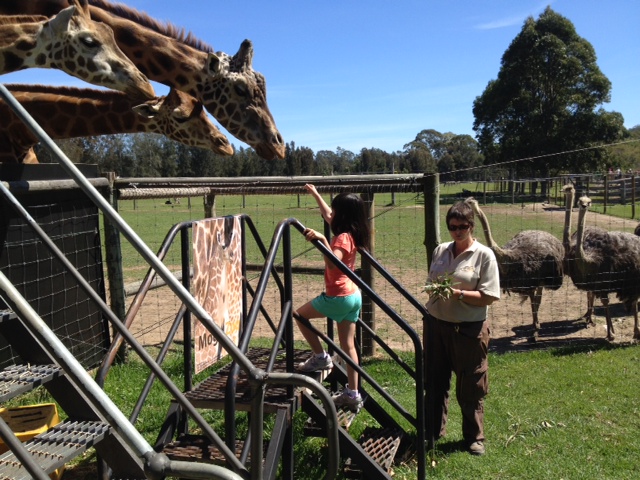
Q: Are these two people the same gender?
A: Yes, all the people are female.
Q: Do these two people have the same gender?
A: Yes, all the people are female.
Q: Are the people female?
A: Yes, all the people are female.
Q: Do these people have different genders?
A: No, all the people are female.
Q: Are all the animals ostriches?
A: No, there are both giraffes and ostriches.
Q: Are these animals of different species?
A: Yes, they are giraffes and ostriches.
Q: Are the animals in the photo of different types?
A: Yes, they are giraffes and ostriches.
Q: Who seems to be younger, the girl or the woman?
A: The girl is younger than the woman.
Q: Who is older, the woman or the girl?
A: The woman is older than the girl.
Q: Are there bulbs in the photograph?
A: No, there are no bulbs.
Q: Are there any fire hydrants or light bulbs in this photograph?
A: No, there are no light bulbs or fire hydrants.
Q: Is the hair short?
A: Yes, the hair is short.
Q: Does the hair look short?
A: Yes, the hair is short.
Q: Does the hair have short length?
A: Yes, the hair is short.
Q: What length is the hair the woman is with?
A: The hair is short.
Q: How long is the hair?
A: The hair is short.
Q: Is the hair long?
A: No, the hair is short.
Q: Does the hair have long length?
A: No, the hair is short.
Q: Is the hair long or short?
A: The hair is short.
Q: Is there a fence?
A: Yes, there is a fence.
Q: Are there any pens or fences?
A: Yes, there is a fence.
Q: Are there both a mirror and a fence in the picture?
A: No, there is a fence but no mirrors.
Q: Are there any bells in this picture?
A: No, there are no bells.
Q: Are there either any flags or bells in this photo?
A: No, there are no bells or flags.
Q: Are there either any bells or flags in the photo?
A: No, there are no bells or flags.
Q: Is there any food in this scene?
A: Yes, there is food.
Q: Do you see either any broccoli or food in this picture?
A: Yes, there is food.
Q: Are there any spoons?
A: No, there are no spoons.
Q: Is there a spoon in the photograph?
A: No, there are no spoons.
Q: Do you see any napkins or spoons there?
A: No, there are no spoons or napkins.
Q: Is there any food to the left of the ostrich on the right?
A: Yes, there is food to the left of the ostrich.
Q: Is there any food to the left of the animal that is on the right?
A: Yes, there is food to the left of the ostrich.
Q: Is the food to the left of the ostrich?
A: Yes, the food is to the left of the ostrich.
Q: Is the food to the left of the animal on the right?
A: Yes, the food is to the left of the ostrich.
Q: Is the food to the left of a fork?
A: No, the food is to the left of the ostrich.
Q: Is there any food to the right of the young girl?
A: Yes, there is food to the right of the girl.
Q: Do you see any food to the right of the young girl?
A: Yes, there is food to the right of the girl.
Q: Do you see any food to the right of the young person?
A: Yes, there is food to the right of the girl.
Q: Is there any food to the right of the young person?
A: Yes, there is food to the right of the girl.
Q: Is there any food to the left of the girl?
A: No, the food is to the right of the girl.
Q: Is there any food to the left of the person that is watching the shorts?
A: No, the food is to the right of the girl.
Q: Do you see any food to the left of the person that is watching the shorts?
A: No, the food is to the right of the girl.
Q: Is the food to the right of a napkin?
A: No, the food is to the right of a girl.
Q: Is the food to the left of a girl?
A: No, the food is to the right of a girl.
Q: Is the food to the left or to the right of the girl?
A: The food is to the right of the girl.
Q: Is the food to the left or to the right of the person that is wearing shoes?
A: The food is to the right of the girl.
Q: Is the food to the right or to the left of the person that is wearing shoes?
A: The food is to the right of the girl.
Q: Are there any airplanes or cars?
A: No, there are no cars or airplanes.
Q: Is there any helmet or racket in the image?
A: No, there are no helmets or rackets.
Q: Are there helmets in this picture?
A: No, there are no helmets.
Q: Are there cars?
A: No, there are no cars.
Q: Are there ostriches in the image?
A: Yes, there is an ostrich.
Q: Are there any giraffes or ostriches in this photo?
A: Yes, there is an ostrich.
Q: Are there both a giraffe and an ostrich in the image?
A: Yes, there are both an ostrich and a giraffe.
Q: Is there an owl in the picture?
A: No, there are no owls.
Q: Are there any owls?
A: No, there are no owls.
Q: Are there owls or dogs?
A: No, there are no owls or dogs.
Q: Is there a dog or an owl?
A: No, there are no owls or dogs.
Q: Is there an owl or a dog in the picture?
A: No, there are no owls or dogs.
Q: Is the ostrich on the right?
A: Yes, the ostrich is on the right of the image.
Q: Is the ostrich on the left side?
A: No, the ostrich is on the right of the image.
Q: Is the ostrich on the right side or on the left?
A: The ostrich is on the right of the image.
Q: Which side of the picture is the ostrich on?
A: The ostrich is on the right of the image.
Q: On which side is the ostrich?
A: The ostrich is on the right of the image.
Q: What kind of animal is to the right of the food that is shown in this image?
A: The animal is an ostrich.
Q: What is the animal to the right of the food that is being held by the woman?
A: The animal is an ostrich.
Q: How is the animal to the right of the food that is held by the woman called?
A: The animal is an ostrich.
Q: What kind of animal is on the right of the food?
A: The animal is an ostrich.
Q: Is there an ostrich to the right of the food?
A: Yes, there is an ostrich to the right of the food.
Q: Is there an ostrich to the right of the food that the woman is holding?
A: Yes, there is an ostrich to the right of the food.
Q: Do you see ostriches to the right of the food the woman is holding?
A: Yes, there is an ostrich to the right of the food.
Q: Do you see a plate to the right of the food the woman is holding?
A: No, there is an ostrich to the right of the food.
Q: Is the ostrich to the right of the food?
A: Yes, the ostrich is to the right of the food.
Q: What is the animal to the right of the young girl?
A: The animal is an ostrich.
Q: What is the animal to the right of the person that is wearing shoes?
A: The animal is an ostrich.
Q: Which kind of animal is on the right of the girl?
A: The animal is an ostrich.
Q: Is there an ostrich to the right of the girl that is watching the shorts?
A: Yes, there is an ostrich to the right of the girl.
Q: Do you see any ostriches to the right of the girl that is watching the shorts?
A: Yes, there is an ostrich to the right of the girl.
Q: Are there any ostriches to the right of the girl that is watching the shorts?
A: Yes, there is an ostrich to the right of the girl.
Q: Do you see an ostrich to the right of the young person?
A: Yes, there is an ostrich to the right of the girl.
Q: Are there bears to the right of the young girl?
A: No, there is an ostrich to the right of the girl.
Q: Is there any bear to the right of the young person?
A: No, there is an ostrich to the right of the girl.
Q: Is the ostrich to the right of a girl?
A: Yes, the ostrich is to the right of a girl.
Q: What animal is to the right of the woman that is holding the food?
A: The animal is an ostrich.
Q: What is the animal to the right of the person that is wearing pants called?
A: The animal is an ostrich.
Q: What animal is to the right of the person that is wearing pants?
A: The animal is an ostrich.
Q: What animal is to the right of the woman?
A: The animal is an ostrich.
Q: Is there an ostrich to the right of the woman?
A: Yes, there is an ostrich to the right of the woman.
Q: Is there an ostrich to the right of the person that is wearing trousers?
A: Yes, there is an ostrich to the right of the woman.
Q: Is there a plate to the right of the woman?
A: No, there is an ostrich to the right of the woman.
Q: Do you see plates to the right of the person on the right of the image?
A: No, there is an ostrich to the right of the woman.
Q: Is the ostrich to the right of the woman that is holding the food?
A: Yes, the ostrich is to the right of the woman.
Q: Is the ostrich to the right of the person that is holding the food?
A: Yes, the ostrich is to the right of the woman.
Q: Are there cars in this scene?
A: No, there are no cars.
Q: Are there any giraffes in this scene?
A: Yes, there is a giraffe.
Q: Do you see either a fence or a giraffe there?
A: Yes, there is a giraffe.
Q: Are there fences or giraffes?
A: Yes, there is a giraffe.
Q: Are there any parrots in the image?
A: No, there are no parrots.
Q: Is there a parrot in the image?
A: No, there are no parrots.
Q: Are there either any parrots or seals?
A: No, there are no parrots or seals.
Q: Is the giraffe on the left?
A: Yes, the giraffe is on the left of the image.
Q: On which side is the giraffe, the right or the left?
A: The giraffe is on the left of the image.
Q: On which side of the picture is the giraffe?
A: The giraffe is on the left of the image.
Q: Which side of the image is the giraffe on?
A: The giraffe is on the left of the image.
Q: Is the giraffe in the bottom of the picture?
A: No, the giraffe is in the top of the image.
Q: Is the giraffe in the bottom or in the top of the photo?
A: The giraffe is in the top of the image.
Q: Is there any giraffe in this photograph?
A: Yes, there is a giraffe.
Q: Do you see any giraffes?
A: Yes, there is a giraffe.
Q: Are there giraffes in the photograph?
A: Yes, there is a giraffe.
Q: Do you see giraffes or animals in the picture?
A: Yes, there is a giraffe.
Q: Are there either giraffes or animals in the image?
A: Yes, there is a giraffe.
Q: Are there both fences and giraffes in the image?
A: Yes, there are both a giraffe and a fence.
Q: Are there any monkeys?
A: No, there are no monkeys.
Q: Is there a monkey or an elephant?
A: No, there are no monkeys or elephants.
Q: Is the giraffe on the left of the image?
A: Yes, the giraffe is on the left of the image.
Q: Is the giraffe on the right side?
A: No, the giraffe is on the left of the image.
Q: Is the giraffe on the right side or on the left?
A: The giraffe is on the left of the image.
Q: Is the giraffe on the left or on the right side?
A: The giraffe is on the left of the image.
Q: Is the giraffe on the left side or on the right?
A: The giraffe is on the left of the image.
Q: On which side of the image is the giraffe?
A: The giraffe is on the left of the image.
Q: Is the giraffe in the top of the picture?
A: Yes, the giraffe is in the top of the image.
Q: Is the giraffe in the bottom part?
A: No, the giraffe is in the top of the image.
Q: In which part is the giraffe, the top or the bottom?
A: The giraffe is in the top of the image.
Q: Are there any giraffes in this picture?
A: Yes, there is a giraffe.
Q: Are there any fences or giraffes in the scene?
A: Yes, there is a giraffe.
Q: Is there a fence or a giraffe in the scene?
A: Yes, there is a giraffe.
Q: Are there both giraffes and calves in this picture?
A: No, there is a giraffe but no calves.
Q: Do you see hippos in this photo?
A: No, there are no hippos.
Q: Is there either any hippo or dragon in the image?
A: No, there are no hippos or dragons.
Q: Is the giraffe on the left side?
A: Yes, the giraffe is on the left of the image.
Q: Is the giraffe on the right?
A: No, the giraffe is on the left of the image.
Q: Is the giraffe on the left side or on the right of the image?
A: The giraffe is on the left of the image.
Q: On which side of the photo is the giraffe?
A: The giraffe is on the left of the image.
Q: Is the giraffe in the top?
A: Yes, the giraffe is in the top of the image.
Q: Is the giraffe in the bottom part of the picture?
A: No, the giraffe is in the top of the image.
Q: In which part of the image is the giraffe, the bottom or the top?
A: The giraffe is in the top of the image.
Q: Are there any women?
A: Yes, there is a woman.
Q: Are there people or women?
A: Yes, there is a woman.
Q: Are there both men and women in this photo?
A: No, there is a woman but no men.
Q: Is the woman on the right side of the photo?
A: Yes, the woman is on the right of the image.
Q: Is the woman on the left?
A: No, the woman is on the right of the image.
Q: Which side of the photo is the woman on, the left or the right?
A: The woman is on the right of the image.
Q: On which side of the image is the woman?
A: The woman is on the right of the image.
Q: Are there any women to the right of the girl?
A: Yes, there is a woman to the right of the girl.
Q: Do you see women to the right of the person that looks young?
A: Yes, there is a woman to the right of the girl.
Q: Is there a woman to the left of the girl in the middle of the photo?
A: No, the woman is to the right of the girl.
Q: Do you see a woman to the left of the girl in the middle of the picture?
A: No, the woman is to the right of the girl.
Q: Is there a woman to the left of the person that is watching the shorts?
A: No, the woman is to the right of the girl.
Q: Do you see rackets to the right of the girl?
A: No, there is a woman to the right of the girl.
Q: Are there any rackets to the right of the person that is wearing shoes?
A: No, there is a woman to the right of the girl.